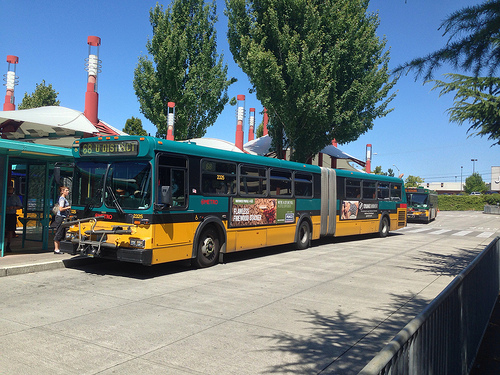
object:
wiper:
[107, 172, 125, 215]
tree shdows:
[392, 243, 496, 278]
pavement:
[1, 212, 498, 374]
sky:
[0, 0, 500, 181]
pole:
[263, 107, 269, 135]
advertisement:
[228, 198, 296, 229]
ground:
[0, 212, 500, 375]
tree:
[135, 1, 237, 139]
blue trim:
[0, 136, 73, 157]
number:
[83, 143, 93, 154]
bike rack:
[53, 216, 130, 257]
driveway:
[0, 210, 500, 374]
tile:
[33, 300, 231, 359]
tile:
[139, 280, 282, 321]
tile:
[305, 248, 401, 276]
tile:
[238, 291, 397, 356]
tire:
[192, 225, 221, 267]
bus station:
[0, 33, 373, 273]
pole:
[2, 55, 18, 110]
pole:
[167, 101, 175, 143]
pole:
[235, 94, 245, 153]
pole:
[249, 108, 255, 142]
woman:
[54, 187, 72, 255]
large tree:
[226, 1, 399, 162]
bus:
[405, 187, 440, 222]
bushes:
[437, 194, 499, 211]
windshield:
[67, 162, 150, 209]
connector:
[319, 167, 336, 237]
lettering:
[201, 199, 218, 204]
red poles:
[85, 36, 100, 126]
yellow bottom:
[64, 207, 408, 267]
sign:
[82, 142, 135, 154]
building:
[0, 35, 100, 257]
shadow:
[252, 290, 430, 375]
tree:
[424, 73, 500, 148]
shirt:
[57, 195, 71, 217]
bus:
[56, 136, 406, 268]